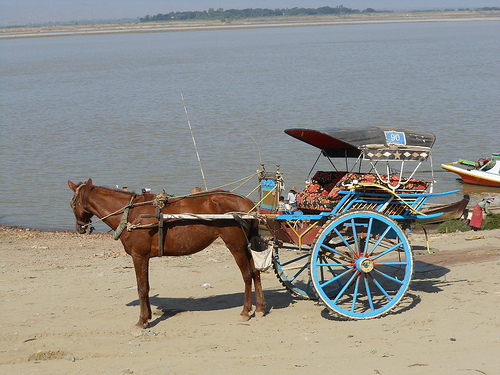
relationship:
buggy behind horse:
[276, 118, 451, 355] [47, 171, 269, 326]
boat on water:
[437, 142, 499, 190] [127, 66, 274, 114]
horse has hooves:
[47, 171, 269, 326] [121, 303, 278, 337]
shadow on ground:
[117, 285, 323, 316] [172, 326, 303, 371]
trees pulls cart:
[140, 6, 373, 25] [235, 116, 465, 325]